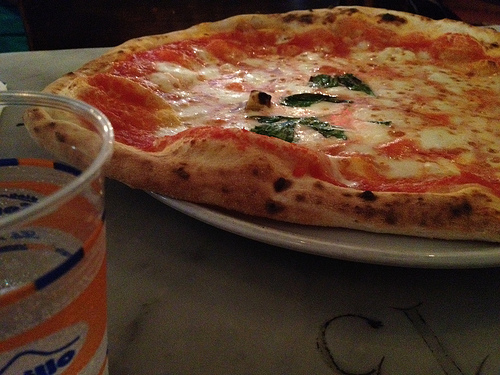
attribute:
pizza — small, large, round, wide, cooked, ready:
[24, 2, 500, 249]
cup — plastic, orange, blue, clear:
[1, 88, 120, 373]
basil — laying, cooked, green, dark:
[248, 70, 391, 149]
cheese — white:
[147, 35, 495, 176]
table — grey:
[4, 27, 498, 374]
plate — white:
[148, 182, 499, 274]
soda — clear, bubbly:
[0, 153, 108, 373]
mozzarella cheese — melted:
[173, 69, 286, 122]